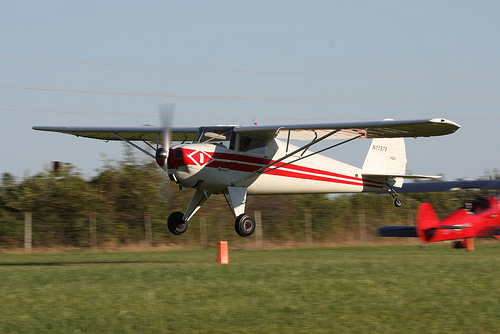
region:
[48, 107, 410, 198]
red and white plane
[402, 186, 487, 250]
red plane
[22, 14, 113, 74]
white clouds in blue sky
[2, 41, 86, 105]
white clouds in blue sky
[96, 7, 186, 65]
white clouds in blue sky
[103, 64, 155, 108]
white clouds in blue sky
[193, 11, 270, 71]
white clouds in blue sky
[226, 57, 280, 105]
white clouds in blue sky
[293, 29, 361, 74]
white clouds in blue sky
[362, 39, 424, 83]
white clouds in blue sky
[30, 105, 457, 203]
Red and white plane.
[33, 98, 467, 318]
Plane is off the ground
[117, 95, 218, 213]
Propeller is spinning.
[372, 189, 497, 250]
Red plane on the ground.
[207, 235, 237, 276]
Red cone in background.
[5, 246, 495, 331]
Flat green field.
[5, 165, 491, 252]
Trees behind fence.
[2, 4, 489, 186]
Skies are clear of clouds.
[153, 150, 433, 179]
Red and white stripe pattern.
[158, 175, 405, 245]
Plane has three wheels.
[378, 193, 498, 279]
red and black plane on th ground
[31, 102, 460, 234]
white plane slightly above ground level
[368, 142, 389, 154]
red numbers on tail of plane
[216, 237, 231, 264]
orange cone on the ground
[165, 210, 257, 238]
black tires on the plane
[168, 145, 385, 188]
red trim on the plane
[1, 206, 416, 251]
wire fence near the bushes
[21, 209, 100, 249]
posts holding up the fence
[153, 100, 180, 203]
propeller on the front of the plane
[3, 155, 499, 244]
trees on the other side of the fence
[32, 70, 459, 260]
airplane just above the ground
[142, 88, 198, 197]
propeller on the airplane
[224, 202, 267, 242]
wheel on the airplane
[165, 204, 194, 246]
wheel on the airplane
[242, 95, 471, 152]
wing on the airplane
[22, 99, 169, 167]
wing on the airplane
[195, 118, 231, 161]
window on the airplane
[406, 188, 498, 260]
airplane on the ground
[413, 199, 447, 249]
tail on the airplane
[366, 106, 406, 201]
tail on the airplane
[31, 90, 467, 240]
A prop plane descending for a landing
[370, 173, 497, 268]
airplane preparing to ascending into the air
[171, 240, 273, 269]
runway green cone for landing strip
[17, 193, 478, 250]
area of fence posts to keep people and animals off of runway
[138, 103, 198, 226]
spinning propeller from plane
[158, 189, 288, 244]
landing gear for plane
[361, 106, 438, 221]
plane rudder to help steer the plane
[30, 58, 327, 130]
power lines for the local airport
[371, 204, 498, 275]
tail fine view of a red plane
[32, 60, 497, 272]
group of planes at an airport